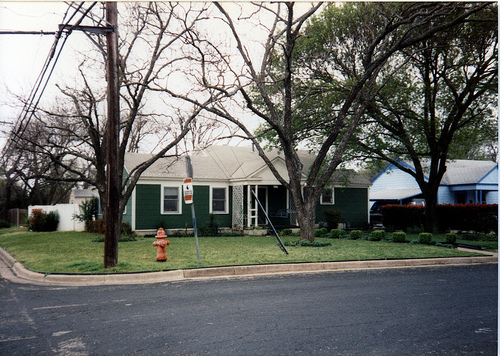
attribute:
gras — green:
[8, 227, 100, 275]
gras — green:
[180, 223, 428, 260]